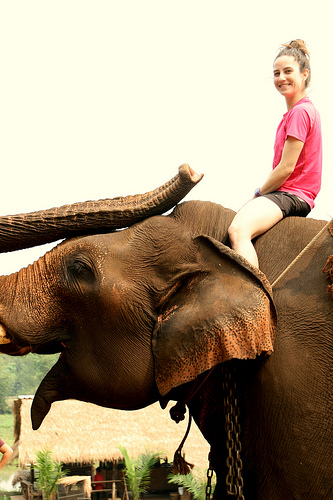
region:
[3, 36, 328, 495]
young lady on an elephant.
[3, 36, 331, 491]
young lady on an elephant.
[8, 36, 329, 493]
young lady on an elephant.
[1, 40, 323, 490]
young lady on an elephant.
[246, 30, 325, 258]
girl sitting on elephant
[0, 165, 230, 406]
elephant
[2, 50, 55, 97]
white clouds in blue sky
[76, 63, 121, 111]
white clouds in blue sky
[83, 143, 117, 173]
white clouds in blue sky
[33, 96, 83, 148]
white clouds in blue sky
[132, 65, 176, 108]
white clouds in blue sky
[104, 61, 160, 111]
white clouds in blue sky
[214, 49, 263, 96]
white clouds in blue sky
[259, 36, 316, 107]
the head of a woman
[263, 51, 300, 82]
the forehead of a woman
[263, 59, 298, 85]
the eyes of a woman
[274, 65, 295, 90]
the nose of a woman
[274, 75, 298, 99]
the mouth of a woman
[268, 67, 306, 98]
the teeth of a woman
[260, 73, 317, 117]
the lips of a woman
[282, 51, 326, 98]
the ear of a woman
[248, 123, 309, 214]
the arm of a woman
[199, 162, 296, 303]
the leg of a woman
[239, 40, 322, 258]
a lady sitting on an elephant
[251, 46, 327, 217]
a lady wearing a red shirt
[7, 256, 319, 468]
an elephant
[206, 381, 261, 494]
a chain coming off the elephant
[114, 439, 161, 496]
a tree in the background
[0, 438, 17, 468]
someone standing next to the elephant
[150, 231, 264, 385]
the ear of the elephant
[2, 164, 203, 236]
the trunk of the elephant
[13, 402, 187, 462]
the roof of the building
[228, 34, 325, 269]
This is a female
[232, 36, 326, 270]
The woman is on an elephant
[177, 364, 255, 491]
Chains hanging from the elephant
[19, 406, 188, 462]
A roof covered in straw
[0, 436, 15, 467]
A man's arm on the left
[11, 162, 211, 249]
Elephant's trunk on its head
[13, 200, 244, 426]
Left side of the elephant's face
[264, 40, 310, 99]
The girl is smiling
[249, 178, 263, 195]
The girl is wearing a watch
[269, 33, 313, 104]
The girl's head is turned to the left